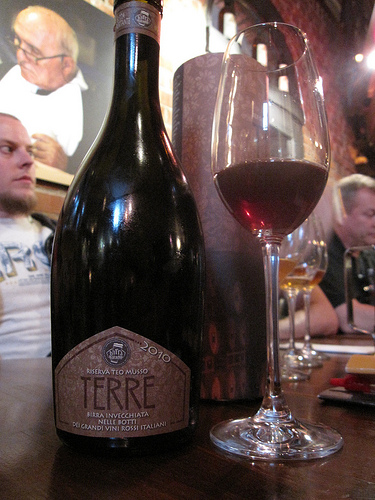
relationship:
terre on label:
[79, 373, 155, 409] [49, 324, 193, 444]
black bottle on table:
[51, 0, 208, 456] [50, 354, 344, 496]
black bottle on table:
[51, 0, 208, 456] [3, 331, 373, 498]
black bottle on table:
[51, 0, 208, 456] [31, 388, 352, 488]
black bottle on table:
[51, 0, 208, 456] [22, 265, 328, 498]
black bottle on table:
[51, 0, 208, 456] [40, 344, 346, 496]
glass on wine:
[208, 20, 345, 463] [212, 160, 327, 239]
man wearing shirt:
[1, 112, 52, 356] [1, 211, 52, 358]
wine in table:
[43, 4, 204, 466] [12, 438, 369, 498]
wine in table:
[212, 160, 330, 249] [3, 331, 373, 498]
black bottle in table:
[51, 0, 208, 456] [3, 331, 373, 498]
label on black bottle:
[46, 323, 201, 451] [51, 0, 208, 456]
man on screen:
[0, 5, 95, 176] [2, 3, 130, 193]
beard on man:
[1, 188, 40, 216] [0, 111, 66, 498]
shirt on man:
[313, 243, 373, 324] [317, 168, 373, 337]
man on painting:
[3, 5, 96, 172] [2, 2, 125, 183]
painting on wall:
[2, 2, 125, 183] [15, 15, 342, 210]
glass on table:
[208, 20, 345, 463] [10, 351, 370, 492]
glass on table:
[276, 209, 321, 384] [10, 351, 370, 492]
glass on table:
[294, 212, 322, 367] [10, 351, 370, 492]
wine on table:
[218, 26, 324, 467] [3, 331, 373, 498]